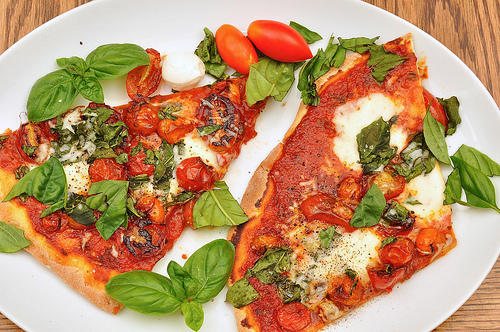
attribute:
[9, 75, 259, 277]
sauce — red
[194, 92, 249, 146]
onion — red, sliced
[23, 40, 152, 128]
basil — green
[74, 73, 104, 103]
leaf — green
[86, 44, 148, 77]
leaf — green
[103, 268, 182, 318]
leaf — green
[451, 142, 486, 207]
leaf — green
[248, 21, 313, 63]
tomato — red , grape 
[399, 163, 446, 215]
cheese — melted, white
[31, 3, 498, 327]
table — brown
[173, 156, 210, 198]
tomato — cooked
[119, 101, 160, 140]
tomato — cooked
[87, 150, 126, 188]
tomato — cooked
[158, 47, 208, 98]
mozzarella cheese — white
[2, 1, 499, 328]
plate — white 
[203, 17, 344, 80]
tomato — red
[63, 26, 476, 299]
plate — white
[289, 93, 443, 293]
cheese — melted, white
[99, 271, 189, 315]
leaf — green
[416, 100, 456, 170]
leaf — green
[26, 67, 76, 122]
leaf — green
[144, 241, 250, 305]
leaf — green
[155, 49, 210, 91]
cheese — white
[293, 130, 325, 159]
sauce — red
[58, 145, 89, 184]
cheese — white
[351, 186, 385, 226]
basil — green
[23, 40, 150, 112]
basil leaf — green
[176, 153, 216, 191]
tomatoes — charred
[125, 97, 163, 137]
tomatoes — charred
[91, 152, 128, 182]
tomatoes — charred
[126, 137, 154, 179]
tomatoes — charred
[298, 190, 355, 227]
tomatoes — charred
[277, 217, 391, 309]
cheese — white, melted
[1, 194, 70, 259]
crust — dark brown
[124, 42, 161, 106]
grape tomato — red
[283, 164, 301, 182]
sauce — Red 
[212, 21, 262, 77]
tomatoes — red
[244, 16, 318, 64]
tomatoes — red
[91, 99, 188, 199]
tomatoes — red